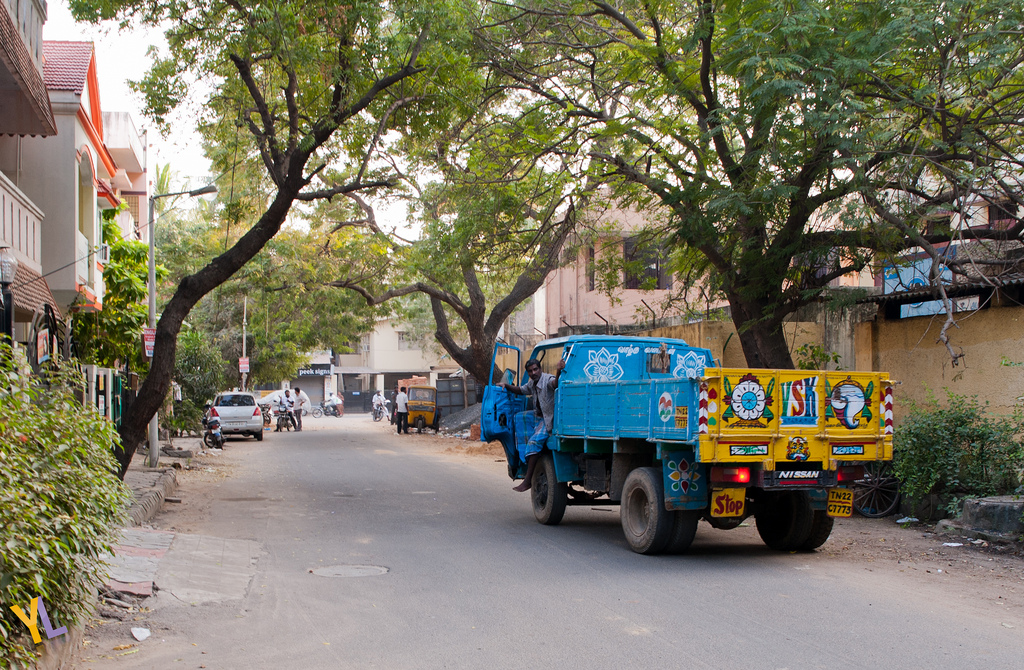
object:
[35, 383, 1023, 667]
black road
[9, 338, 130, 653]
bushes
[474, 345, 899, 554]
automobile blue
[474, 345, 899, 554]
automobile yellow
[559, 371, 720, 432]
blue panel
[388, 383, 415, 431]
white shirt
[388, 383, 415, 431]
person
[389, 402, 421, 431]
black pants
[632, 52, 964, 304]
green leaves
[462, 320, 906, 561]
roadway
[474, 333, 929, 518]
truck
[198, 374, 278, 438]
car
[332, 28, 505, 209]
wall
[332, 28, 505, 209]
building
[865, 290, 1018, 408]
wall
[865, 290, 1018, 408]
building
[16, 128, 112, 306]
wall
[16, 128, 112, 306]
building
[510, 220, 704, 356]
wall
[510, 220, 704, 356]
building